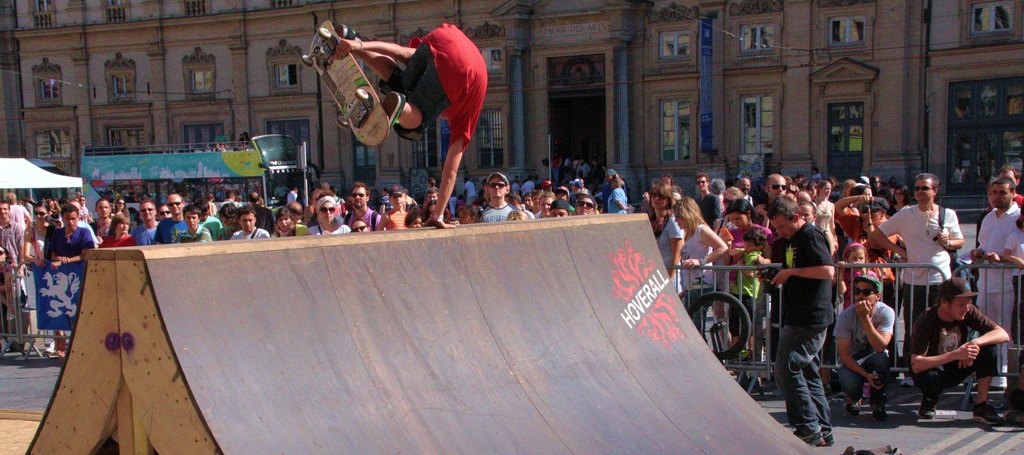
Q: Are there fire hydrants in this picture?
A: No, there are no fire hydrants.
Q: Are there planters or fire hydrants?
A: No, there are no fire hydrants or planters.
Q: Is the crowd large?
A: Yes, the crowd is large.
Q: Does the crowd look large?
A: Yes, the crowd is large.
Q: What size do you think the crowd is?
A: The crowd is large.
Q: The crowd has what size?
A: The crowd is large.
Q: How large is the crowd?
A: The crowd is large.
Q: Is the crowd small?
A: No, the crowd is large.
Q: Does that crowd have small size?
A: No, the crowd is large.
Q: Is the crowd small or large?
A: The crowd is large.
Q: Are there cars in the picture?
A: No, there are no cars.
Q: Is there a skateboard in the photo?
A: Yes, there is a skateboard.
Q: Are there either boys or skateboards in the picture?
A: Yes, there is a skateboard.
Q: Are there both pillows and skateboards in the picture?
A: No, there is a skateboard but no pillows.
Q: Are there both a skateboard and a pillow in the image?
A: No, there is a skateboard but no pillows.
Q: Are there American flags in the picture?
A: No, there are no American flags.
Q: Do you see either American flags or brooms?
A: No, there are no American flags or brooms.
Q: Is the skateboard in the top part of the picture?
A: Yes, the skateboard is in the top of the image.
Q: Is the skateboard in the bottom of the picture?
A: No, the skateboard is in the top of the image.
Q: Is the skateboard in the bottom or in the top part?
A: The skateboard is in the top of the image.